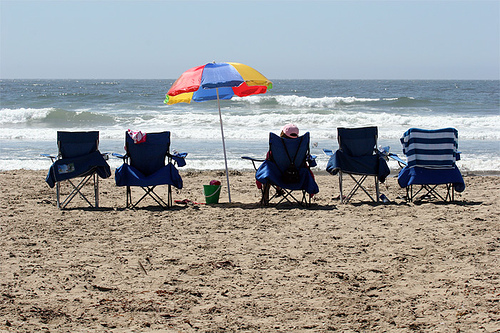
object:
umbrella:
[162, 59, 273, 205]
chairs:
[389, 127, 469, 206]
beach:
[2, 167, 499, 332]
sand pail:
[201, 181, 223, 206]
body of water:
[0, 78, 500, 170]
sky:
[2, 0, 499, 81]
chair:
[48, 130, 113, 209]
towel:
[399, 128, 462, 171]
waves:
[0, 93, 500, 142]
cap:
[283, 123, 301, 140]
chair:
[240, 132, 319, 204]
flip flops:
[174, 196, 206, 207]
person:
[276, 124, 320, 199]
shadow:
[61, 206, 117, 215]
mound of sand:
[185, 165, 239, 177]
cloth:
[125, 128, 147, 146]